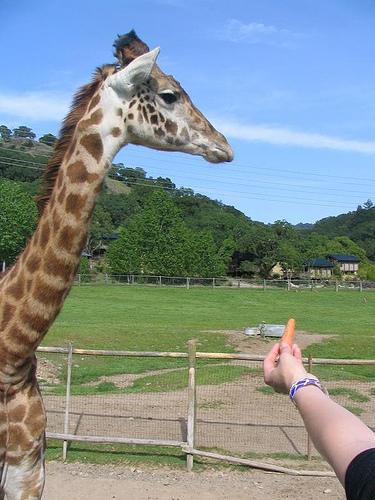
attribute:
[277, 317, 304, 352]
carrot — orange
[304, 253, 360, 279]
house — two story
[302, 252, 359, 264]
roof — gray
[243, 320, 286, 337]
water trough — metal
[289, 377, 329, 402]
bracelet — white, blue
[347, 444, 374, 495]
shirt — black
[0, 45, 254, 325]
giraffe — white, paper, patterned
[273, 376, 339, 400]
bracelet — purple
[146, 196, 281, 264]
trees — Whole bunch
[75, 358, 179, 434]
wire — black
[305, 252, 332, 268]
roof — black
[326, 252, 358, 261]
roof — black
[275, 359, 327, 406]
wrist band — Blue, White